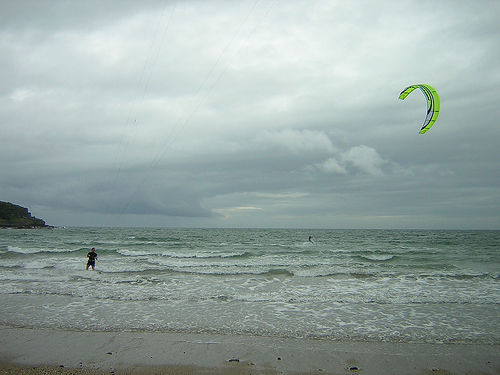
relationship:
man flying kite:
[73, 223, 121, 297] [385, 75, 454, 134]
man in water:
[73, 223, 121, 297] [40, 226, 224, 286]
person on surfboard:
[299, 224, 330, 249] [308, 240, 322, 250]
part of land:
[4, 191, 29, 235] [4, 171, 67, 257]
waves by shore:
[266, 261, 326, 294] [278, 340, 412, 363]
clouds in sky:
[98, 41, 200, 116] [4, 9, 460, 76]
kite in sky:
[385, 75, 454, 134] [4, 9, 460, 76]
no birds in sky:
[6, 5, 94, 36] [4, 9, 460, 76]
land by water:
[4, 171, 67, 257] [40, 226, 224, 286]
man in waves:
[73, 223, 121, 297] [266, 261, 326, 294]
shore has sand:
[278, 340, 412, 363] [42, 328, 159, 370]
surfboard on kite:
[308, 240, 322, 250] [385, 75, 454, 134]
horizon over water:
[40, 186, 479, 225] [40, 226, 224, 286]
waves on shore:
[266, 261, 326, 294] [278, 340, 412, 363]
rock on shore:
[218, 347, 238, 374] [278, 340, 412, 363]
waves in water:
[266, 261, 326, 294] [40, 226, 224, 286]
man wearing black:
[73, 223, 121, 297] [88, 252, 111, 275]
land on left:
[4, 171, 67, 257] [13, 114, 69, 206]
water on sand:
[40, 226, 224, 286] [42, 328, 159, 370]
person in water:
[299, 224, 330, 249] [40, 226, 224, 286]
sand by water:
[42, 328, 159, 370] [40, 226, 224, 286]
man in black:
[73, 223, 121, 297] [88, 252, 111, 275]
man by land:
[73, 223, 121, 297] [4, 171, 67, 257]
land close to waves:
[4, 171, 67, 257] [266, 261, 326, 294]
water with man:
[40, 226, 224, 286] [73, 223, 121, 297]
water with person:
[40, 226, 224, 286] [299, 224, 330, 249]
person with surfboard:
[299, 224, 330, 249] [308, 240, 322, 250]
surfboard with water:
[308, 240, 322, 250] [40, 226, 224, 286]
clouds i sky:
[98, 41, 200, 116] [4, 9, 460, 76]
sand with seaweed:
[42, 328, 159, 370] [328, 353, 374, 372]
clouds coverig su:
[98, 41, 200, 116] [203, 194, 268, 219]